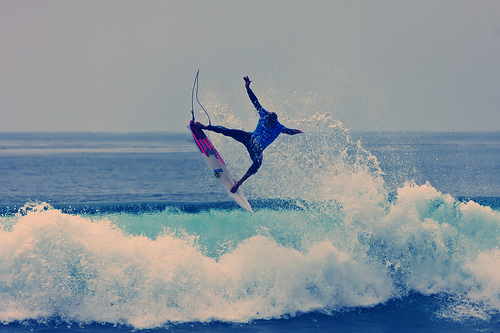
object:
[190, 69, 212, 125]
tether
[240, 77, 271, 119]
mans arms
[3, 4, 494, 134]
sky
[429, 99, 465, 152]
ground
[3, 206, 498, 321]
wave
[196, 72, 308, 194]
person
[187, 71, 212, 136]
end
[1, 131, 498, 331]
ocean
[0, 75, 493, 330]
splashing water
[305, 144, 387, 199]
splashes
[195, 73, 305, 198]
man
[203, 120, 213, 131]
strap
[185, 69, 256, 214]
surfing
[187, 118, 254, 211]
board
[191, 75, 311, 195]
surfer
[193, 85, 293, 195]
wetsuit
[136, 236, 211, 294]
splash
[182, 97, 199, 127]
piece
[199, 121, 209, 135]
ankle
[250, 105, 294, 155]
shirt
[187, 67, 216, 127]
cord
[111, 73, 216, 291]
air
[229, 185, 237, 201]
ankle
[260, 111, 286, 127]
head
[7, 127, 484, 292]
water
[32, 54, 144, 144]
air